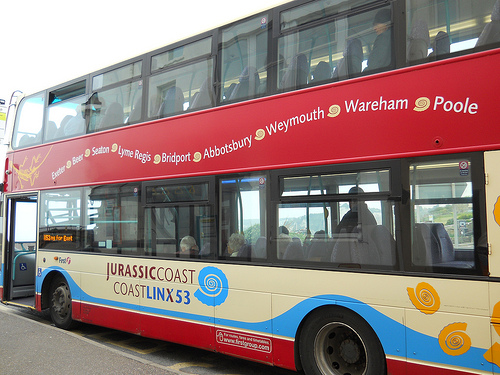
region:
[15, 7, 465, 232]
the bus has two stories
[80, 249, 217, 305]
it says jurassic coast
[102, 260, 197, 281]
the text is red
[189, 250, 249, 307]
the symbol is a swirl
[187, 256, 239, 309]
the symbol is blue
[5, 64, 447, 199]
the bus is red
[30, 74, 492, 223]
the text is white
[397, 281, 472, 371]
the swirls are orange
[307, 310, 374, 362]
the tires are black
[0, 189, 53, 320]
the door is open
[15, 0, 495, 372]
this is a bus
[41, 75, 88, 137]
this is a window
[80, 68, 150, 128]
this is a window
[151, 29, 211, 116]
this is a window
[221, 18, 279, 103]
this is a window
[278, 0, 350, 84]
this is a window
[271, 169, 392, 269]
this is a window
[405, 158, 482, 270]
this is a window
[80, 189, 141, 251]
this is a window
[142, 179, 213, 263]
this is a window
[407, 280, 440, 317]
the bus has orange swirls on its side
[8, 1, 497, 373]
the bus is a double decked with red white blue and red as its main colors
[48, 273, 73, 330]
the tire is black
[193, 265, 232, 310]
this swirl is blue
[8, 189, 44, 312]
the door to the bus is open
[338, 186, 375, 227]
you can see somebody standing up inside of the bus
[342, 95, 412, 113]
the letters are white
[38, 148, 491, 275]
the bus has very clear windows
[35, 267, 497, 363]
light blue runs along the bottom of the bus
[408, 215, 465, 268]
the seats are gray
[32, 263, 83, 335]
Wheel of a bus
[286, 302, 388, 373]
Wheel of a bus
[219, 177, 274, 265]
Window of a bus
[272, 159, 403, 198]
Window of a bus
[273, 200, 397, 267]
Window of a bus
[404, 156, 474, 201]
Window of a bus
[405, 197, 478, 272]
Window of a bus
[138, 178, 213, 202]
Window of a bus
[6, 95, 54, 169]
window of a bus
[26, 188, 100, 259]
window of a bus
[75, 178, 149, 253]
window of a bus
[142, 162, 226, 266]
window of a bus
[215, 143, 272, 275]
window of a bus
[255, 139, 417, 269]
window of a bus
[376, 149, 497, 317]
window of a bus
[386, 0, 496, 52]
window of a bus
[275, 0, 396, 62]
window of a bus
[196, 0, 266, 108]
window of a bus